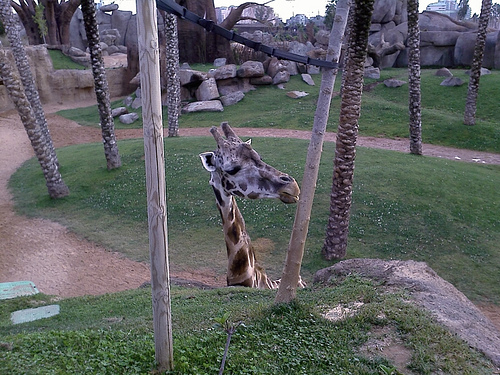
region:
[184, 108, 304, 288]
Giraffe peaking over a hill.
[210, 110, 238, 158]
Giraffe has two horns.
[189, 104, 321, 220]
Giraffe is curious about the limb of a tree.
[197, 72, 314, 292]
Giraffe is living in a zoo.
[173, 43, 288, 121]
Rocks in the giraffe's enclosure.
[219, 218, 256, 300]
Giraffe with brown spots.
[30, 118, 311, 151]
Path leading around the enclosure.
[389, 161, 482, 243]
Green grass in the enclosure.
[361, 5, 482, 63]
Very large rocks in the background.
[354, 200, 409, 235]
Small white flowers growing in the grass.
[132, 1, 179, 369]
one light colored straight wooden pole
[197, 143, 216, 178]
one light colored giraffe ear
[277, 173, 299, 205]
one brown giraffe snout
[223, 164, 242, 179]
one large dark giraffe eye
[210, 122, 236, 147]
two light brown giraffe horns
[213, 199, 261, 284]
one brown giraffe neck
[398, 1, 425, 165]
one textured thin tree trunk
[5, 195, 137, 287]
light brown dirt path next to grass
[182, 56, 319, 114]
several gray boulders next to green grass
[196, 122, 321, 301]
giraffe next to thin brown tree trunk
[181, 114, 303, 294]
SPOTTED GIRAFFE HIDING BEHIND HILL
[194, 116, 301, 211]
HEAD OF SPOTTED GIRAFFE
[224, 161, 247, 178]
EYE OF SPOTTED GIRAFFE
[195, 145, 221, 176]
EAR OF SPOTTED GIRAFFE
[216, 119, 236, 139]
HORN OF SPOTTED GIRAFFE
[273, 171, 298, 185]
NOSE OF SPOTTED GIRAFFE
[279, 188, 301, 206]
MOUTH OF SPOTTED GIRAFFE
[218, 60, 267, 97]
PILE OF BOULDERS BEHIND GIRAFFE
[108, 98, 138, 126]
BOULDERS BEHIND GIRAFFE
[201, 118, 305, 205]
a giraffe's head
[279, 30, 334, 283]
a small gray tree trunk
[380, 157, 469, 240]
green grass on a lawn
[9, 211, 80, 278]
a brown dirt path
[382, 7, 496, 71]
boulders and rocks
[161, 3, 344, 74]
a black strap on a tree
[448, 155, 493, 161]
a water puddle in the dirt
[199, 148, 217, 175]
a right ear of a giraffe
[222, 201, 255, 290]
a neck of a giraffe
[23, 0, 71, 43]
a large brown tree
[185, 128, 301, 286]
tall giraffe in zoo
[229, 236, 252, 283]
brown spots on giraffe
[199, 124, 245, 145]
small horns on giraffe's head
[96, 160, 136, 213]
green grass in field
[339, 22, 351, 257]
trunk of tall tree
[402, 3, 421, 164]
trunk of tall tree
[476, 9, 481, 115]
trunk of tall tree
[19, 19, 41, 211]
trunk of tall tree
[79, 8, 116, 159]
trunk of tall tree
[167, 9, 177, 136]
trunk of tall tree